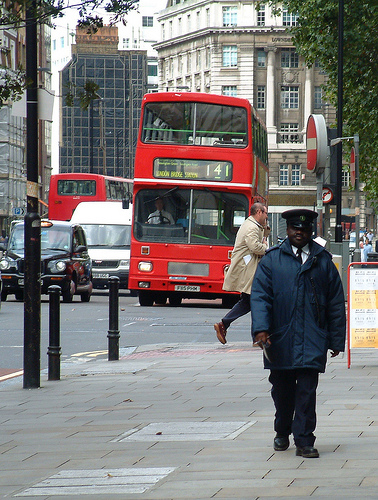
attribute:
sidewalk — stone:
[1, 346, 362, 498]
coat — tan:
[217, 209, 270, 298]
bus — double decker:
[123, 86, 277, 318]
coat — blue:
[248, 235, 349, 373]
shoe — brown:
[212, 320, 228, 344]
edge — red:
[305, 115, 315, 139]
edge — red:
[304, 148, 317, 170]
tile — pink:
[119, 343, 261, 358]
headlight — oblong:
[129, 250, 233, 285]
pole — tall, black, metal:
[15, 3, 48, 215]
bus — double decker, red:
[203, 159, 234, 183]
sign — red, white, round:
[300, 112, 338, 177]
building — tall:
[153, 0, 332, 191]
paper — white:
[242, 251, 254, 266]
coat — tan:
[223, 216, 263, 298]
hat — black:
[275, 207, 319, 230]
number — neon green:
[198, 161, 234, 180]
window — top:
[143, 99, 258, 160]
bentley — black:
[3, 211, 96, 303]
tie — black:
[292, 248, 307, 263]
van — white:
[69, 199, 128, 297]